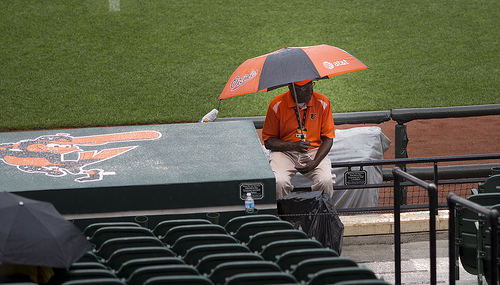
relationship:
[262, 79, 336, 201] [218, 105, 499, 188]
man sitting on railing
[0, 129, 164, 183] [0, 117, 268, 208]
logo on top of dugout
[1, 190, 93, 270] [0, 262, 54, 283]
black umbrella used by fan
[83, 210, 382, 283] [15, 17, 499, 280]
seats in stadium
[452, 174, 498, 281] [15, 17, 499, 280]
seats in stadium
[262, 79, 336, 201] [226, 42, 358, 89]
man holding umbrella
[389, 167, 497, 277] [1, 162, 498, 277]
railing in stadium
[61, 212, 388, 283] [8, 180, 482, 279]
seats in stands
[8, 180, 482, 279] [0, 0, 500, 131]
stands at green field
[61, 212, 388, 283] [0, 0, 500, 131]
seats at green field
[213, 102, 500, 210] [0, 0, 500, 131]
railing at green field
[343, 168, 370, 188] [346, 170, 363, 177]
signs with words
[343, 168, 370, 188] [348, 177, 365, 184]
signs with words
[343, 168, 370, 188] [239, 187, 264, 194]
signs with words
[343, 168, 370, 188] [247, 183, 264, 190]
signs with words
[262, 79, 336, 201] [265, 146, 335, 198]
man wearing pants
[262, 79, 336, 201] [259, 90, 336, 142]
man wearing shirt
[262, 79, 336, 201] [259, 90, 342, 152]
man wearing shirt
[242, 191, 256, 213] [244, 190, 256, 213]
bottle of water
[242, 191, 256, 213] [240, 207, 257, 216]
bottle in holder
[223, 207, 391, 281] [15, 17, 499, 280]
seats in stadium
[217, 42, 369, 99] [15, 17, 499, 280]
umbrella in stadium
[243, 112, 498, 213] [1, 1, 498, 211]
dirt area field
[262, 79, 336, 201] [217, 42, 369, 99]
man holding umbrella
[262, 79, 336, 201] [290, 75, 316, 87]
man wearing hat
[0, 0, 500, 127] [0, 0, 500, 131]
green field on green field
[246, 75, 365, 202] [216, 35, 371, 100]
man under umbrella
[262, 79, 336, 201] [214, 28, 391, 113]
man holding umbrella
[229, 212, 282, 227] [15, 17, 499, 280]
seat in stadium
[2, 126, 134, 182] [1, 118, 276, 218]
logo on roof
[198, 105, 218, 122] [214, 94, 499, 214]
bottle on railing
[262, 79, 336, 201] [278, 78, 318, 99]
man wearing glasses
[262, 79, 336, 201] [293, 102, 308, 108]
man wearing white undershirt